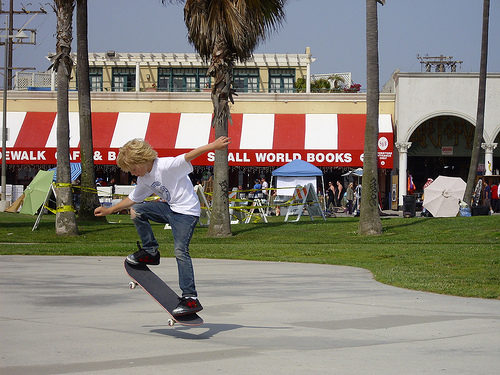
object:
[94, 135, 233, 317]
boy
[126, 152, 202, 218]
shirt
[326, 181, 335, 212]
woman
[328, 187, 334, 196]
shirt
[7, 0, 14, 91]
pole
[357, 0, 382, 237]
pole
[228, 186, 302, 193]
tape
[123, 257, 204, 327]
skateboard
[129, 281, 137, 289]
wheel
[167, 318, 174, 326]
wheel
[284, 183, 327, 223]
warning sign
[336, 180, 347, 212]
people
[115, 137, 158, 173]
blonde hair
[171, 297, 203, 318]
sneaker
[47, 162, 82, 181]
umbrella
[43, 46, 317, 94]
building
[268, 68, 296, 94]
windows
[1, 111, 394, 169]
canopy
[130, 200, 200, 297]
jeans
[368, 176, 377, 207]
graffiti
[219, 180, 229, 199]
graffiti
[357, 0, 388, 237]
tree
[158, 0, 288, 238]
tree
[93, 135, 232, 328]
skateboarding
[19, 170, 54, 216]
parasol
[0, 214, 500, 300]
grass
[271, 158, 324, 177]
canopy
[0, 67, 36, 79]
gadgets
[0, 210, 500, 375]
ground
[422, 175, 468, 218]
parasol